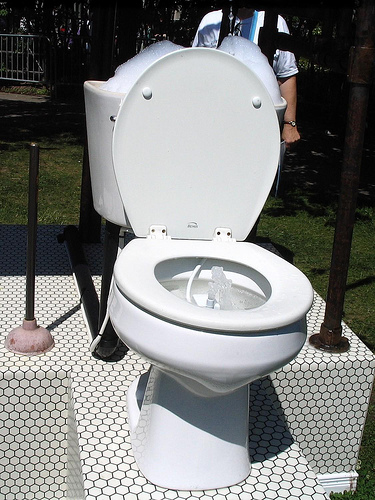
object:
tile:
[0, 280, 374, 500]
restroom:
[0, 41, 375, 498]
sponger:
[3, 317, 56, 356]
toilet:
[78, 45, 315, 492]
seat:
[114, 223, 315, 335]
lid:
[108, 43, 280, 245]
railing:
[0, 30, 51, 84]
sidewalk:
[0, 79, 61, 103]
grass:
[0, 102, 373, 495]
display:
[0, 25, 373, 498]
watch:
[281, 119, 301, 127]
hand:
[280, 120, 300, 147]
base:
[127, 344, 254, 491]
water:
[195, 259, 251, 322]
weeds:
[326, 473, 369, 498]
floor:
[0, 275, 372, 500]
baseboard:
[316, 469, 359, 494]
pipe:
[62, 222, 126, 363]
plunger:
[3, 318, 56, 355]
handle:
[16, 139, 40, 323]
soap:
[91, 34, 283, 104]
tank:
[78, 71, 289, 232]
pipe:
[311, 3, 375, 353]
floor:
[280, 363, 374, 479]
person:
[189, 4, 299, 144]